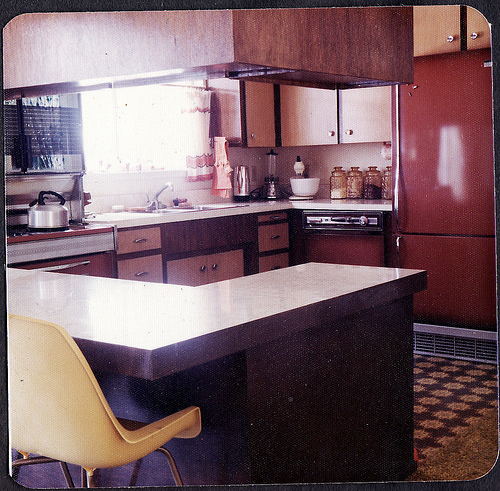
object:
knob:
[328, 131, 337, 137]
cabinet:
[278, 82, 338, 147]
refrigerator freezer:
[389, 47, 500, 371]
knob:
[199, 265, 206, 272]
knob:
[212, 262, 218, 270]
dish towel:
[209, 137, 234, 200]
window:
[75, 78, 211, 174]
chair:
[1, 307, 210, 491]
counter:
[4, 258, 430, 489]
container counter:
[362, 164, 382, 201]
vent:
[411, 322, 498, 365]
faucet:
[143, 181, 176, 213]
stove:
[1, 220, 117, 264]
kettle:
[26, 189, 71, 234]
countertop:
[82, 193, 397, 236]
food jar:
[346, 166, 364, 200]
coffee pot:
[230, 162, 253, 203]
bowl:
[288, 176, 323, 199]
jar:
[326, 163, 348, 202]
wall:
[267, 141, 398, 202]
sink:
[107, 200, 250, 217]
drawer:
[115, 226, 164, 256]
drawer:
[117, 254, 164, 284]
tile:
[416, 370, 443, 391]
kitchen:
[0, 0, 500, 491]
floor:
[409, 346, 500, 482]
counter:
[286, 197, 393, 270]